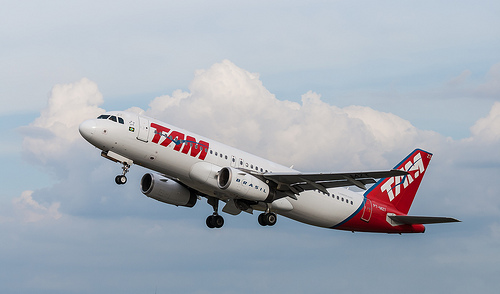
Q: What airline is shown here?
A: TAM.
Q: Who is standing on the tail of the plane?
A: No one.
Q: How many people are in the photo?
A: Zero.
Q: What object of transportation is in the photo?
A: Airplane.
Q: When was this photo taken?
A: Daytime.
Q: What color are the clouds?
A: White.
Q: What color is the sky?
A: Blue.